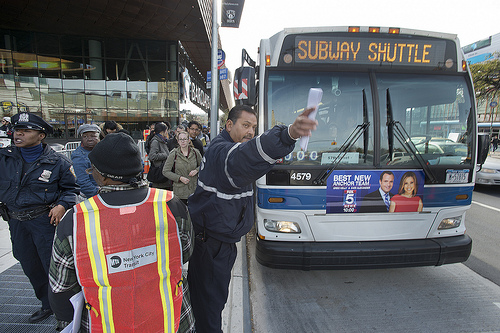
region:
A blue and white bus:
[230, 27, 497, 277]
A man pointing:
[186, 98, 315, 331]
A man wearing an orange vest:
[52, 137, 192, 331]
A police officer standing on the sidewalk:
[0, 107, 80, 331]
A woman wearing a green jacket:
[158, 129, 205, 203]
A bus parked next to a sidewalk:
[234, 31, 485, 283]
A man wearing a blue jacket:
[175, 94, 320, 331]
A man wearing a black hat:
[37, 129, 207, 331]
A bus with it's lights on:
[232, 23, 487, 270]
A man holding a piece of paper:
[164, 79, 338, 331]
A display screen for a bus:
[294, 35, 447, 70]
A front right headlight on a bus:
[261, 217, 301, 235]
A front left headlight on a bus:
[437, 214, 462, 231]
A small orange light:
[345, 25, 360, 33]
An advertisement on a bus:
[325, 168, 423, 214]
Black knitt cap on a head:
[86, 131, 143, 180]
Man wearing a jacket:
[189, 103, 319, 330]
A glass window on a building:
[83, 90, 108, 107]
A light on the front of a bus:
[267, 197, 285, 204]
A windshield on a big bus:
[265, 66, 472, 183]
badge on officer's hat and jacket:
[0, 111, 80, 204]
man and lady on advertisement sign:
[324, 169, 428, 216]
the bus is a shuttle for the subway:
[291, 37, 457, 65]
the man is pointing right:
[205, 100, 321, 191]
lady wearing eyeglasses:
[172, 132, 198, 151]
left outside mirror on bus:
[474, 121, 495, 174]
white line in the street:
[470, 183, 497, 223]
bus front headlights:
[260, 213, 467, 237]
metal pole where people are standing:
[203, 0, 223, 140]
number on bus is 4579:
[287, 169, 318, 184]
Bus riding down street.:
[202, 10, 497, 325]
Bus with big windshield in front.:
[258, 21, 492, 267]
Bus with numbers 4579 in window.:
[254, 19, 479, 274]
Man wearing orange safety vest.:
[41, 129, 201, 331]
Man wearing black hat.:
[86, 132, 151, 189]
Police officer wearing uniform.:
[0, 109, 72, 331]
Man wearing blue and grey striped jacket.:
[186, 103, 300, 328]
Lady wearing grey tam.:
[67, 121, 117, 192]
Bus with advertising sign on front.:
[253, 17, 480, 271]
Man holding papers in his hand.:
[185, 84, 325, 331]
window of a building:
[148, 38, 186, 59]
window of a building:
[123, 35, 158, 69]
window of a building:
[107, 39, 129, 61]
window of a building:
[89, 43, 125, 70]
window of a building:
[64, 45, 94, 71]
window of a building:
[27, 37, 72, 77]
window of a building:
[0, 73, 36, 104]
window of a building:
[37, 78, 69, 105]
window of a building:
[65, 75, 107, 109]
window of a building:
[100, 84, 141, 120]